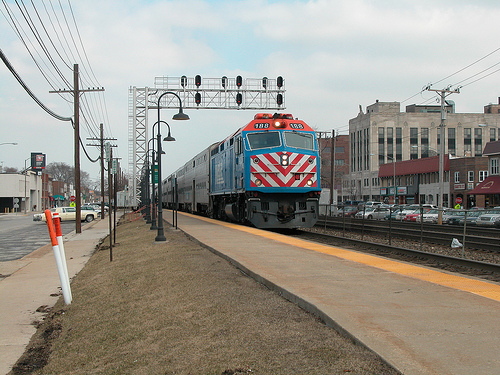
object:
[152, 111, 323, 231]
train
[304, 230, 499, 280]
track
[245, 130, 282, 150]
window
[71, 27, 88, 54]
wire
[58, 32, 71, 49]
wire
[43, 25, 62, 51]
wire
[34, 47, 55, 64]
wire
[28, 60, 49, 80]
wire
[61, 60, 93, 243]
pole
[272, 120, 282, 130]
headlight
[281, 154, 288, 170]
headlight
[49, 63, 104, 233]
electric pole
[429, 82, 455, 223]
electric pole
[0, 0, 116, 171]
wires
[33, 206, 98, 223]
car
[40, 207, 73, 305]
poles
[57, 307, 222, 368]
ground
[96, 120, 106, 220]
pole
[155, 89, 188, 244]
street lamp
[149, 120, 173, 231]
street lamp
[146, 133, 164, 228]
street lamp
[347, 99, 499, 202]
building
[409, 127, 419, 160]
windows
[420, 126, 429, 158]
windows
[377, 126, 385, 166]
windows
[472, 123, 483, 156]
windows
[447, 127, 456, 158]
windows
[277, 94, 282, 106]
light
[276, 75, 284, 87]
light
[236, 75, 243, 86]
light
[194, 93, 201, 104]
light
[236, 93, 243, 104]
light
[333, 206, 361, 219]
cars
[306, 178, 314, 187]
headlight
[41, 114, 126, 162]
lines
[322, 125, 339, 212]
pole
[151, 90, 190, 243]
lamp